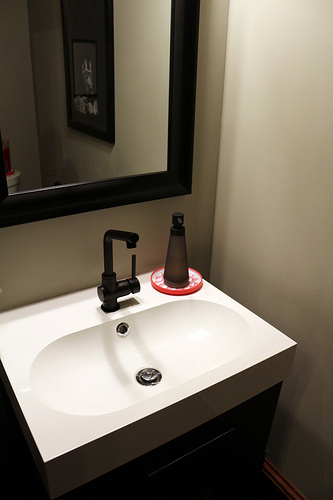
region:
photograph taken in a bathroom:
[15, 9, 309, 489]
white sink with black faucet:
[21, 210, 279, 469]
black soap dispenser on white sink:
[154, 208, 208, 296]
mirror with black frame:
[9, 0, 222, 234]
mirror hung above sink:
[4, 0, 204, 240]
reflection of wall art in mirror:
[57, 0, 144, 151]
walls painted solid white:
[236, 14, 313, 131]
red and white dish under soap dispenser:
[152, 211, 206, 300]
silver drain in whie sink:
[132, 357, 180, 394]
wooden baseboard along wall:
[263, 458, 296, 491]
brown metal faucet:
[82, 222, 146, 316]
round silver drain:
[132, 365, 165, 387]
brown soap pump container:
[160, 206, 196, 288]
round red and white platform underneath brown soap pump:
[146, 262, 203, 295]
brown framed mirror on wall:
[0, 1, 212, 231]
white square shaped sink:
[4, 257, 299, 496]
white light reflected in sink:
[171, 320, 216, 354]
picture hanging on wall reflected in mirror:
[52, 0, 134, 154]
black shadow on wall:
[34, 132, 82, 184]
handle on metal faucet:
[125, 251, 146, 297]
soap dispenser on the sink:
[166, 209, 196, 300]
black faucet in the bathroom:
[90, 221, 143, 317]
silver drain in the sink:
[132, 367, 162, 386]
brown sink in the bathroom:
[28, 442, 213, 488]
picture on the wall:
[49, 3, 135, 149]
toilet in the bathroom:
[8, 157, 28, 193]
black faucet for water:
[94, 221, 147, 323]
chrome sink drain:
[127, 361, 175, 390]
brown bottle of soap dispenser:
[152, 198, 201, 297]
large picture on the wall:
[51, 18, 127, 147]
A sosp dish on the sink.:
[158, 213, 199, 282]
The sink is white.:
[29, 322, 288, 378]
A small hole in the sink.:
[106, 316, 141, 338]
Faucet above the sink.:
[84, 229, 144, 310]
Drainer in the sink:
[129, 351, 169, 384]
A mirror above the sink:
[24, 19, 207, 190]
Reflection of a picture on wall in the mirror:
[54, 22, 116, 126]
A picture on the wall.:
[53, 12, 124, 124]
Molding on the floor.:
[265, 458, 318, 497]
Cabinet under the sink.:
[178, 453, 256, 492]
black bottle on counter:
[151, 209, 198, 280]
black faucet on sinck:
[106, 230, 160, 276]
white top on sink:
[58, 316, 304, 377]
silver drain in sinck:
[128, 362, 167, 388]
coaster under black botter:
[144, 270, 200, 303]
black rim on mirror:
[90, 160, 205, 208]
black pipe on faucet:
[103, 267, 149, 296]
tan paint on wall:
[20, 225, 84, 264]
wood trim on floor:
[281, 455, 303, 497]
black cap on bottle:
[167, 208, 189, 223]